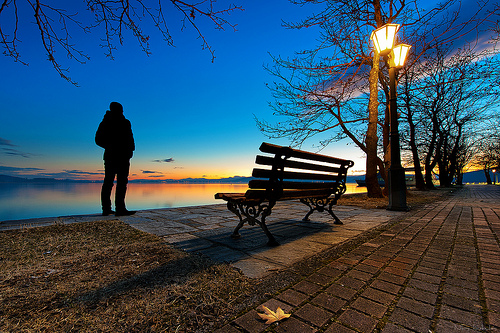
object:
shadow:
[173, 219, 329, 256]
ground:
[268, 231, 374, 284]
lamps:
[367, 22, 413, 70]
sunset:
[145, 168, 245, 182]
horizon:
[0, 58, 500, 222]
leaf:
[255, 304, 292, 326]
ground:
[206, 287, 250, 327]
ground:
[1, 233, 105, 331]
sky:
[1, 0, 500, 177]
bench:
[213, 141, 355, 246]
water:
[0, 181, 367, 219]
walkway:
[243, 197, 499, 329]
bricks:
[336, 263, 482, 319]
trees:
[246, 0, 499, 199]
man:
[93, 101, 136, 216]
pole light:
[368, 23, 412, 212]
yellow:
[367, 22, 412, 69]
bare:
[354, 55, 499, 206]